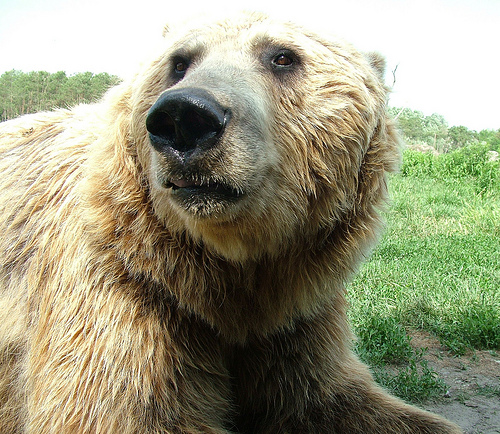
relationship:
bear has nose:
[1, 10, 460, 434] [144, 88, 227, 148]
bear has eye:
[1, 10, 460, 434] [270, 50, 295, 68]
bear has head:
[1, 10, 460, 434] [114, 8, 397, 267]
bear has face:
[1, 10, 460, 434] [146, 31, 317, 227]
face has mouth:
[146, 31, 317, 227] [162, 169, 233, 204]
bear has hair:
[1, 10, 460, 434] [4, 8, 455, 433]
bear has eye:
[1, 10, 460, 434] [170, 56, 189, 73]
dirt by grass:
[354, 316, 499, 429] [354, 166, 495, 400]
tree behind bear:
[3, 73, 19, 118] [1, 10, 460, 434]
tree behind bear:
[15, 76, 36, 116] [1, 10, 460, 434]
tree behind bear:
[39, 74, 58, 112] [1, 10, 460, 434]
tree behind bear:
[59, 74, 72, 113] [1, 10, 460, 434]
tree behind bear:
[84, 76, 96, 103] [1, 10, 460, 434]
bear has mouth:
[1, 10, 460, 434] [162, 169, 233, 204]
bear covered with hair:
[1, 10, 460, 434] [4, 8, 455, 433]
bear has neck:
[1, 10, 460, 434] [106, 74, 376, 323]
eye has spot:
[270, 50, 295, 68] [279, 56, 285, 63]